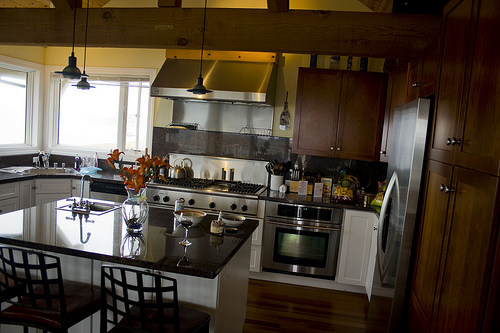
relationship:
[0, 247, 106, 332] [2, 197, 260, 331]
chair at island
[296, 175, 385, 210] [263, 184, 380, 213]
food items on counter top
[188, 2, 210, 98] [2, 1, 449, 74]
light hanging from ceiling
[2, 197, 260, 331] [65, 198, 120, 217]
island with a sink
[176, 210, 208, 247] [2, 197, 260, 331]
wine glass on island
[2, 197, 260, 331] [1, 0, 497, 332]
island in middle of kitchen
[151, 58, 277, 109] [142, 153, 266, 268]
vent hood above stove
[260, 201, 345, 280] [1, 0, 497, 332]
oven in kitchen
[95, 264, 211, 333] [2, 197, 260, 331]
chair by island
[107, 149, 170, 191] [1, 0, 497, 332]
flowers in middle of kitchen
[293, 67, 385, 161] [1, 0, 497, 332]
cupboards in kitchen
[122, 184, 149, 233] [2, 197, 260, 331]
vase on island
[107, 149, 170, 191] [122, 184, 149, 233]
flowers in vase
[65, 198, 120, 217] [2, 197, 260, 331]
sink set into island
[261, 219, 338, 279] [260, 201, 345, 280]
door of oven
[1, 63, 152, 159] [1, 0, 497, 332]
windows in corner of kitchen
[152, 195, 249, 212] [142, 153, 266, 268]
knobs on stove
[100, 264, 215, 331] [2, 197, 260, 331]
chair at island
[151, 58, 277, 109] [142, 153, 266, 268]
vent hood over stove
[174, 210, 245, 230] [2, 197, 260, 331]
bowls on island